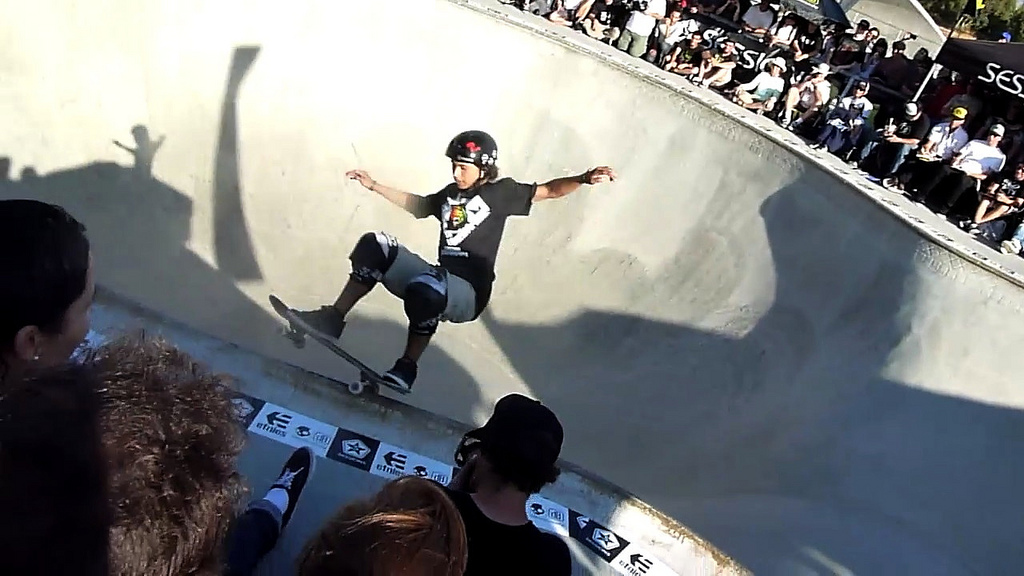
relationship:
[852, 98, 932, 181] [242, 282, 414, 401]
person watching skateboard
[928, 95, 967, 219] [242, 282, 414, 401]
person watching skateboard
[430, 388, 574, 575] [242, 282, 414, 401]
person watching skateboard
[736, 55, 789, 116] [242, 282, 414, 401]
person watching skateboard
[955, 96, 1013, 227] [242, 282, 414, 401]
person watching skateboard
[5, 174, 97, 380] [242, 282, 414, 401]
person watching skateboard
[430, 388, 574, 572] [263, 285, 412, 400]
person watching skateboard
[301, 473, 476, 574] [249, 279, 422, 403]
person watching skateboard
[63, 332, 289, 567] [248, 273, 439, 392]
person watching skateboard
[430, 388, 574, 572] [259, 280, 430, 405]
person watching skateboard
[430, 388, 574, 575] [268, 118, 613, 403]
person watching skate boarder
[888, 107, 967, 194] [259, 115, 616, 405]
person watching skateboarder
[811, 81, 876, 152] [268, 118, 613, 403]
person watching skate boarder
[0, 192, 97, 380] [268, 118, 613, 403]
person watching skate boarder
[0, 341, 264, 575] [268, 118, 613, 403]
person watching skate boarder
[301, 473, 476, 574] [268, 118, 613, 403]
person watching skate boarder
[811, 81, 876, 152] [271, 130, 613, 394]
person watching skateboarder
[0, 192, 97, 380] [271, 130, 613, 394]
person watching skateboarder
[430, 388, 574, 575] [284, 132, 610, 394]
person watching man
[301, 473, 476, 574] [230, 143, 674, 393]
person watching skateboarder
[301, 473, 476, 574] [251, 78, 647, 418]
person watching skate boarder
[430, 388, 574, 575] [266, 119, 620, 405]
person sitting down person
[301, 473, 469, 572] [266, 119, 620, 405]
person sitting down person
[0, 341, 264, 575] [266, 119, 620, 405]
person sitting down person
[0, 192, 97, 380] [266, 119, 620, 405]
person sitting down person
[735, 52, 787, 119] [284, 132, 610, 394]
person sitting down man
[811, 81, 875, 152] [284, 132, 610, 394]
person sitting down man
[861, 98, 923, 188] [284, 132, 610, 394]
person sitting down man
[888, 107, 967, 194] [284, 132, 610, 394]
person sitting down man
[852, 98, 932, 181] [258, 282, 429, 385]
person watching skateboard